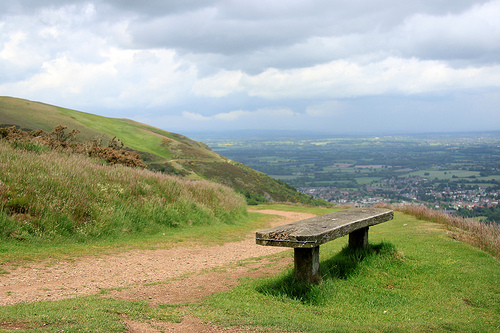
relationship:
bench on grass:
[255, 202, 393, 292] [203, 202, 499, 331]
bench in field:
[255, 202, 393, 292] [2, 96, 499, 331]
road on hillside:
[0, 201, 325, 309] [0, 92, 324, 259]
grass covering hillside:
[1, 141, 248, 234] [0, 125, 263, 219]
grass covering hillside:
[1, 129, 248, 218] [0, 120, 241, 239]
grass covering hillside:
[381, 195, 498, 255] [375, 200, 498, 255]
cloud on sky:
[235, 61, 500, 98] [369, 35, 439, 82]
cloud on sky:
[193, 61, 248, 100] [3, 0, 498, 137]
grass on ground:
[331, 254, 499, 332] [0, 94, 499, 331]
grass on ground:
[7, 97, 202, 167] [0, 94, 499, 331]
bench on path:
[255, 202, 393, 292] [2, 203, 312, 302]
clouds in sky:
[24, 9, 481, 111] [3, 0, 498, 137]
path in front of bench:
[18, 204, 236, 330] [255, 203, 393, 278]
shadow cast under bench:
[256, 237, 383, 304] [255, 202, 393, 292]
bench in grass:
[255, 202, 393, 292] [2, 97, 498, 329]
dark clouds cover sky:
[88, 2, 416, 62] [13, 59, 498, 131]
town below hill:
[207, 140, 499, 210] [5, 97, 498, 331]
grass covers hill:
[1, 141, 248, 234] [1, 94, 357, 274]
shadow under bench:
[256, 237, 383, 304] [255, 202, 393, 292]